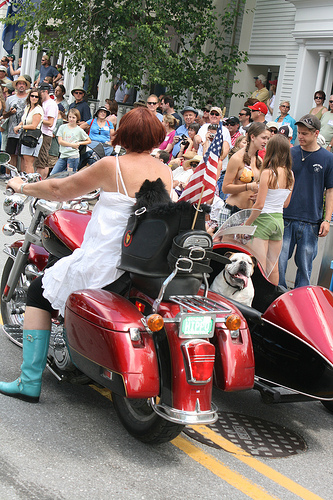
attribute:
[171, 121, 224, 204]
flag — small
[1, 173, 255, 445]
motorcycle — red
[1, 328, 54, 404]
boot — blue, light blue, long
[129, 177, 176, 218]
cat — black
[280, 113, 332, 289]
man — talking, young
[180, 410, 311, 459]
man hole cover — closed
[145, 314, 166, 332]
brake light — red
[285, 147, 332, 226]
t-shirt — dark blue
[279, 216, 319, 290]
jeans — worn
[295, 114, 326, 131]
hat — brown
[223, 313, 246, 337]
tail light — red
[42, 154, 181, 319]
dress — white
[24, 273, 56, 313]
leggings — black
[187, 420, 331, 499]
line — yellow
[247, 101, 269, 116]
hat — red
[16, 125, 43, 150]
handbag` — black